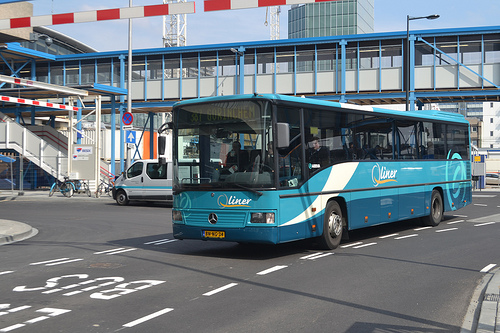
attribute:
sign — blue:
[118, 117, 144, 156]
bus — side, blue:
[169, 87, 463, 254]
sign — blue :
[101, 104, 152, 135]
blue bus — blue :
[143, 96, 498, 249]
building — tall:
[283, 0, 384, 40]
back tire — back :
[421, 187, 446, 229]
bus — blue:
[180, 94, 468, 258]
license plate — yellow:
[202, 226, 228, 241]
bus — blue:
[182, 86, 450, 261]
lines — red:
[123, 114, 131, 124]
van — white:
[117, 148, 164, 218]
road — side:
[92, 209, 142, 233]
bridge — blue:
[14, 39, 495, 116]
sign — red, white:
[3, 90, 80, 120]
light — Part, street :
[424, 12, 441, 20]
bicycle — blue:
[48, 180, 75, 195]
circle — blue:
[121, 108, 133, 122]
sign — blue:
[115, 105, 142, 128]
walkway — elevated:
[51, 26, 484, 106]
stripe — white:
[287, 157, 364, 222]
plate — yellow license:
[200, 226, 227, 240]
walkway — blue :
[105, 25, 483, 101]